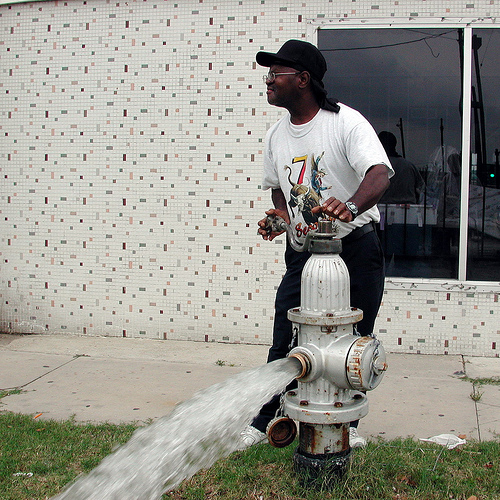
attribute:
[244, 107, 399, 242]
shirt — white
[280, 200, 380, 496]
hydrant — white, fire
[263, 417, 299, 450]
cap — rusty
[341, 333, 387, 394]
cap — white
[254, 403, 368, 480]
base — rusty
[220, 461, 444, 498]
grass — green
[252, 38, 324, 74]
hat — black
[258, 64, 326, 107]
head — man's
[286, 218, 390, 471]
hydrant — silver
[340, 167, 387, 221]
arm — man's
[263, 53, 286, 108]
face — man's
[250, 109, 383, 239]
shirt — white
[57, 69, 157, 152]
tiles — small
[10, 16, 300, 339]
wall — store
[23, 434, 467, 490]
grass — green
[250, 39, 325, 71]
cap — black, baseball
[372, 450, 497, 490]
grass — green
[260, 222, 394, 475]
fountain — old, white, water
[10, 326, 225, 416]
sidewalk — concrete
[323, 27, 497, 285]
window — store, large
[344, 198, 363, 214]
watch — man's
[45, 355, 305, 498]
stream — large, powerful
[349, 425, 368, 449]
shoe — white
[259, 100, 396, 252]
shirt — white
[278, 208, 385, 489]
fire hydrant — white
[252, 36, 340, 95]
hat — black